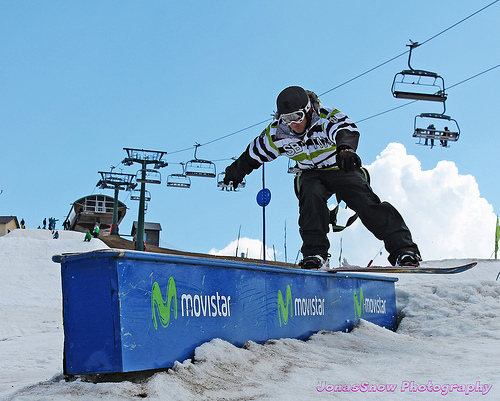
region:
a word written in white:
[180, 286, 232, 322]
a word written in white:
[291, 288, 330, 322]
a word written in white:
[361, 291, 397, 318]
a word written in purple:
[310, 370, 358, 396]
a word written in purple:
[355, 372, 395, 392]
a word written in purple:
[400, 375, 491, 399]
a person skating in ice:
[213, 59, 478, 323]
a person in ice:
[78, 224, 95, 244]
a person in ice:
[48, 225, 66, 240]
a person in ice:
[40, 213, 49, 229]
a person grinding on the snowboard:
[102, 71, 483, 357]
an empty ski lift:
[381, 34, 449, 107]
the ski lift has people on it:
[401, 96, 483, 171]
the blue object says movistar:
[52, 239, 255, 366]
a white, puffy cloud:
[339, 138, 498, 266]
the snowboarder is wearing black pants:
[277, 150, 424, 284]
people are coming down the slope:
[20, 210, 109, 262]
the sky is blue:
[5, 6, 495, 218]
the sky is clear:
[4, 11, 274, 114]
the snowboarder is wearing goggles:
[266, 78, 353, 190]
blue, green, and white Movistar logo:
[94, 237, 286, 349]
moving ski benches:
[383, 55, 479, 166]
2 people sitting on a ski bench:
[408, 94, 468, 159]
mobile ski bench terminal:
[57, 173, 188, 236]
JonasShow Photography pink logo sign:
[300, 352, 497, 400]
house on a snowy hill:
[3, 209, 36, 249]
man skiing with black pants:
[198, 67, 493, 298]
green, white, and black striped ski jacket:
[217, 95, 377, 185]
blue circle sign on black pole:
[248, 177, 288, 259]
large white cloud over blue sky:
[422, 149, 497, 241]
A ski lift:
[385, 37, 462, 109]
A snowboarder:
[217, 76, 496, 315]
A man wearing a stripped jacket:
[223, 75, 426, 280]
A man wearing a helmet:
[219, 57, 402, 289]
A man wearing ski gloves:
[213, 85, 400, 249]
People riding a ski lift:
[404, 100, 470, 158]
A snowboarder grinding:
[54, 87, 473, 367]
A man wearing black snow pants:
[212, 62, 422, 291]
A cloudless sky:
[2, 0, 219, 135]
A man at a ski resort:
[24, 2, 471, 390]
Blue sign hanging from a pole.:
[253, 183, 276, 217]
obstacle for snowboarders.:
[51, 248, 418, 388]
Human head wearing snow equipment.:
[273, 82, 313, 143]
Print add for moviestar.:
[142, 270, 237, 335]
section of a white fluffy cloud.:
[403, 162, 459, 209]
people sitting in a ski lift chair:
[400, 110, 467, 167]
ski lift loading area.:
[42, 173, 133, 260]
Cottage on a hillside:
[0, 208, 26, 244]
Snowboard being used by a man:
[260, 232, 488, 299]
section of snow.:
[408, 328, 445, 343]